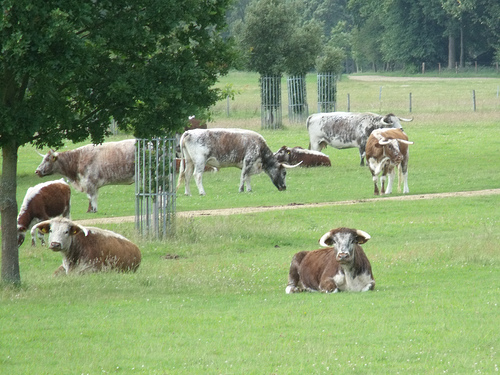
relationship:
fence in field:
[208, 92, 484, 112] [1, 64, 481, 373]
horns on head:
[314, 226, 369, 246] [314, 224, 371, 263]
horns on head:
[317, 226, 373, 246] [316, 226, 370, 261]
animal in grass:
[364, 123, 415, 195] [13, 68, 481, 371]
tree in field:
[0, 6, 226, 322] [4, 110, 498, 373]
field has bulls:
[4, 110, 498, 373] [3, 114, 423, 286]